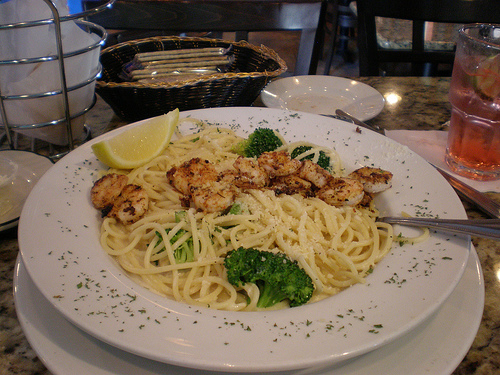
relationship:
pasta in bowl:
[92, 117, 429, 312] [18, 106, 472, 373]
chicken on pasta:
[89, 172, 151, 225] [92, 117, 429, 312]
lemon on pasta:
[92, 107, 181, 168] [92, 117, 429, 312]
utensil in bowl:
[368, 216, 499, 241] [18, 106, 472, 373]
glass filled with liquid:
[445, 22, 500, 182] [445, 51, 500, 182]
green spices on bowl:
[27, 110, 457, 356] [18, 106, 472, 373]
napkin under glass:
[381, 128, 499, 194] [445, 22, 500, 182]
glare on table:
[382, 88, 405, 109] [1, 75, 500, 372]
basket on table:
[96, 35, 288, 122] [1, 75, 500, 372]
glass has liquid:
[445, 22, 500, 182] [445, 51, 500, 182]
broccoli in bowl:
[146, 127, 330, 306] [18, 106, 472, 373]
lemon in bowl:
[92, 107, 181, 168] [18, 106, 472, 373]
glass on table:
[445, 22, 500, 182] [1, 75, 500, 372]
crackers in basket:
[117, 43, 237, 83] [96, 35, 288, 122]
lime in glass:
[471, 53, 499, 103] [445, 22, 500, 182]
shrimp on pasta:
[90, 148, 393, 225] [92, 117, 429, 312]